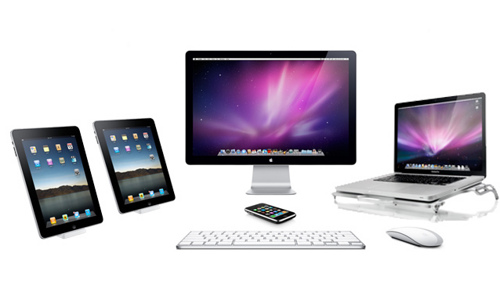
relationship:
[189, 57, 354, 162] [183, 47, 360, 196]
screen on computer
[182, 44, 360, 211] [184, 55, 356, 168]
computer with screen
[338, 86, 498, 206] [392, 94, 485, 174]
computer with screen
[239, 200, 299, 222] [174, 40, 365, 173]
phone next to monitor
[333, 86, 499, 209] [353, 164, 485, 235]
laptop on a stand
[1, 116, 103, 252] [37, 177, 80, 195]
tablet picture of mountain